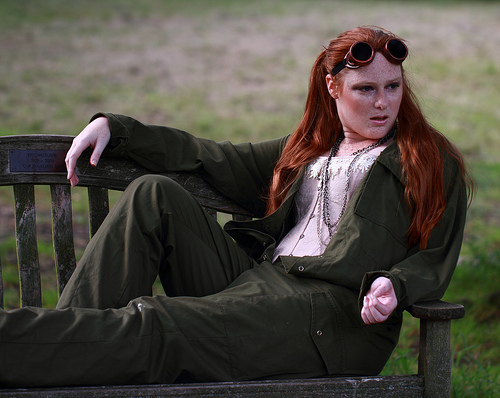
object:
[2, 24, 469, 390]
woman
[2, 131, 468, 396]
bench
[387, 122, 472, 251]
hair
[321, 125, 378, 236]
necklace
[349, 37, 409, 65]
goggles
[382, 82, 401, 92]
eye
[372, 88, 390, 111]
nose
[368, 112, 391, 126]
mouth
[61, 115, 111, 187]
hand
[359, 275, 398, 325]
hand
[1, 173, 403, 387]
pants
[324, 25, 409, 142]
head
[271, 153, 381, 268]
top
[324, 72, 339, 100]
ear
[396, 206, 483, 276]
arm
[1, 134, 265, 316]
back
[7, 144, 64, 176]
plaque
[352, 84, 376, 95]
eye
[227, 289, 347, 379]
pocket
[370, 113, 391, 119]
lip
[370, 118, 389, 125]
lip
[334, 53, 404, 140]
face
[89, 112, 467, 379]
jacket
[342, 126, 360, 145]
neck